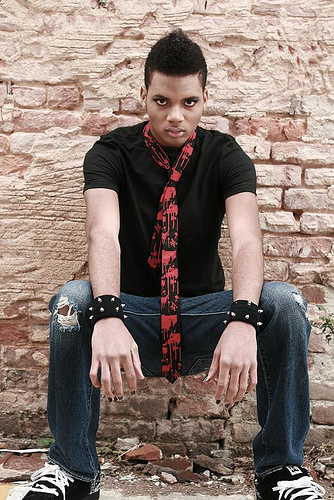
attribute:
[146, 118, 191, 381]
tie — red, black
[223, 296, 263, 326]
cuffs — black, spiky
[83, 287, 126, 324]
cuffs — black, spiky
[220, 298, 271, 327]
cuffs — spiky, black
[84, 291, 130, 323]
cuffs — spiky, black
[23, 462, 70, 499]
shoe laces — white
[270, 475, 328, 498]
shoe laces — white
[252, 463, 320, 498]
shoe — black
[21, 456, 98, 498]
shoe — black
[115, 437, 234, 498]
bricks — broken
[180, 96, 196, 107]
liner — black, eye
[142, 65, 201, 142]
face — human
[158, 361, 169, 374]
spot — red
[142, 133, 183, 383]
tie — one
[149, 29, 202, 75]
cut — Mohawk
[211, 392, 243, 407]
polish — some, black, fingernail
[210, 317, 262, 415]
hand — human, male, one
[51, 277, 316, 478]
jeans — ripped, blue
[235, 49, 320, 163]
wall — brick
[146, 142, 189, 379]
tie — black, red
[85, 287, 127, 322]
wristband — spiked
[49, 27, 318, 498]
man — one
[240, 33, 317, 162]
wall — one, brick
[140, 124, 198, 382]
tie — black, red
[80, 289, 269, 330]
bands — wrist, studded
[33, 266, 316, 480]
jeans — blue, holey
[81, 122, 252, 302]
shirt — black, short-sleeved